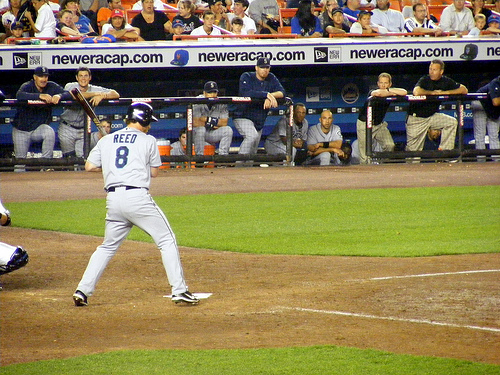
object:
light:
[130, 108, 144, 120]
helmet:
[128, 102, 159, 125]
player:
[471, 76, 500, 163]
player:
[406, 59, 469, 164]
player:
[357, 73, 409, 165]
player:
[265, 102, 310, 167]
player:
[303, 109, 346, 166]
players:
[169, 127, 192, 171]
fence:
[0, 93, 500, 172]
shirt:
[266, 114, 308, 155]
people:
[188, 80, 234, 168]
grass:
[0, 186, 500, 257]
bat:
[70, 87, 108, 137]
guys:
[75, 187, 190, 297]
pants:
[12, 124, 56, 171]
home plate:
[162, 293, 213, 300]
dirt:
[1, 162, 500, 368]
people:
[57, 67, 120, 161]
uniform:
[75, 127, 189, 295]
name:
[114, 134, 137, 144]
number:
[115, 146, 129, 168]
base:
[0, 0, 500, 375]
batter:
[73, 102, 201, 306]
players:
[264, 103, 308, 167]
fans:
[1, 1, 500, 43]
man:
[234, 57, 287, 168]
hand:
[95, 120, 111, 136]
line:
[277, 306, 500, 332]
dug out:
[0, 60, 500, 172]